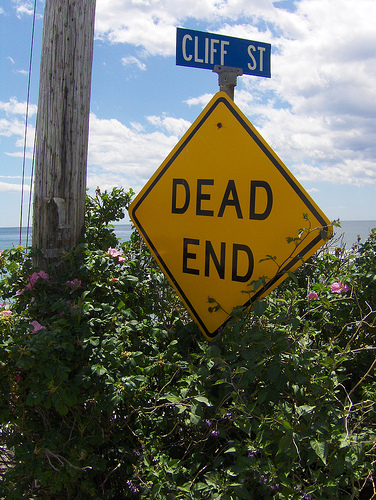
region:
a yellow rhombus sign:
[132, 86, 343, 368]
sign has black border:
[124, 93, 338, 347]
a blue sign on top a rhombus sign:
[122, 9, 345, 337]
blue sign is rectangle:
[160, 21, 280, 80]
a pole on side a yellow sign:
[16, 1, 118, 442]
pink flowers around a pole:
[14, 241, 130, 332]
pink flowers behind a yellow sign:
[300, 260, 357, 309]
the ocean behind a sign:
[0, 201, 373, 281]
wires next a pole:
[6, 0, 100, 277]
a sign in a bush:
[4, 19, 370, 492]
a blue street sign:
[174, 25, 271, 78]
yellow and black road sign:
[127, 90, 333, 342]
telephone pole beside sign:
[29, 0, 96, 297]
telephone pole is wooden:
[24, 2, 94, 272]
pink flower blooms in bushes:
[1, 246, 351, 332]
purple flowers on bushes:
[124, 405, 312, 497]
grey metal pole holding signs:
[211, 64, 243, 98]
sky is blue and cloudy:
[2, 0, 374, 227]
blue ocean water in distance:
[1, 218, 375, 306]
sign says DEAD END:
[168, 166, 275, 286]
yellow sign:
[120, 107, 325, 312]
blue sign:
[169, 30, 272, 79]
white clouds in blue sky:
[0, 7, 38, 50]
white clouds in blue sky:
[1, 80, 33, 120]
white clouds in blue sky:
[2, 156, 35, 204]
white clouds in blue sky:
[110, 9, 174, 60]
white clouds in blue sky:
[107, 122, 144, 162]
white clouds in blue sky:
[293, 9, 367, 79]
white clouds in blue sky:
[264, 88, 355, 160]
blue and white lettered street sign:
[168, 22, 275, 91]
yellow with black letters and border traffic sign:
[127, 89, 333, 334]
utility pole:
[30, 0, 94, 261]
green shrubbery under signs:
[50, 319, 363, 488]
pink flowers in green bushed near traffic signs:
[301, 269, 362, 310]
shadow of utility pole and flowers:
[12, 285, 114, 452]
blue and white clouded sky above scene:
[1, 0, 366, 220]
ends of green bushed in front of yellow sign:
[198, 195, 343, 323]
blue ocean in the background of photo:
[1, 209, 366, 278]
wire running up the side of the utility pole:
[16, 0, 43, 267]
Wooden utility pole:
[30, 3, 89, 257]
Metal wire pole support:
[16, 2, 39, 250]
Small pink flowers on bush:
[308, 279, 353, 303]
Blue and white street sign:
[166, 23, 276, 79]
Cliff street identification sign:
[168, 25, 274, 79]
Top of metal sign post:
[211, 66, 245, 98]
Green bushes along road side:
[10, 247, 370, 491]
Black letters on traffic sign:
[165, 176, 274, 282]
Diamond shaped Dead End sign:
[122, 88, 333, 342]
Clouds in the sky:
[102, 8, 192, 191]